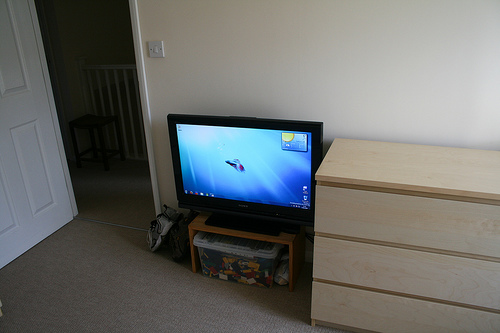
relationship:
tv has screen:
[168, 112, 324, 221] [176, 123, 314, 210]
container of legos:
[192, 230, 286, 288] [196, 247, 272, 286]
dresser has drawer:
[311, 135, 498, 321] [312, 182, 498, 259]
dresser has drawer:
[311, 135, 498, 321] [311, 233, 499, 313]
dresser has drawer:
[311, 135, 498, 321] [309, 280, 494, 328]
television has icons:
[168, 112, 324, 221] [183, 189, 214, 200]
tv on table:
[168, 112, 324, 221] [188, 211, 308, 290]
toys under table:
[196, 247, 272, 286] [188, 211, 308, 290]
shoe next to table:
[169, 223, 190, 265] [188, 211, 308, 290]